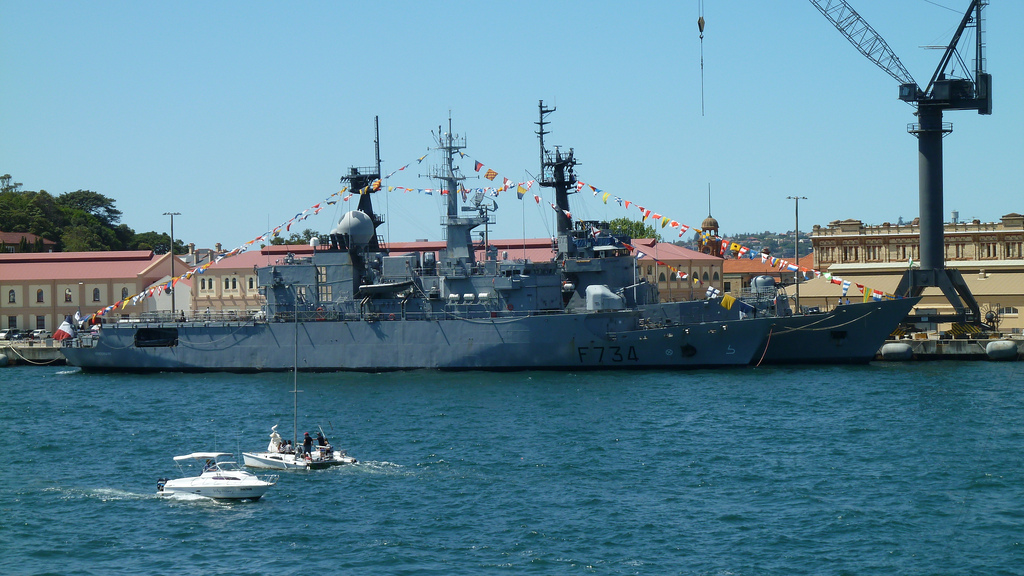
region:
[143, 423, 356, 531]
white boats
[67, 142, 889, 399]
large boat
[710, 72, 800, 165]
white clouds in blue sky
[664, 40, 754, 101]
white clouds in blue sky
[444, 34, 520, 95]
white clouds in blue sky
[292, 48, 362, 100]
white clouds in blue sky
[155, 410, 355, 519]
boats on the water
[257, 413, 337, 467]
people on the boat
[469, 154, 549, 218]
flags on the line above the boat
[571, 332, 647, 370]
F734 written on the side of the boat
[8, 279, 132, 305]
windows on the building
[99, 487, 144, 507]
white crashing waves on the water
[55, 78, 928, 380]
ship in the water in front of the houses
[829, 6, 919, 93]
crane in the air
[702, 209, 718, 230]
steeple on top of the building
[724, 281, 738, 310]
yellow flag on the boat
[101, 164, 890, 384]
large ship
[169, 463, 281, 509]
white boat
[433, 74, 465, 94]
white clouds in blue sky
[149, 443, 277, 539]
white boat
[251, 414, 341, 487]
boat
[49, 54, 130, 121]
white clouds in the blue sky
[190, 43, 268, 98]
white clouds in the blue sky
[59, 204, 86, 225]
green leaves on the tree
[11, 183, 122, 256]
green leaves on the tree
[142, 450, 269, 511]
small white boat in blue water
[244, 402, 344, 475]
small white boat in blue water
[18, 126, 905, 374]
large gray boat in blue water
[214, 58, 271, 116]
white clouds in blue sky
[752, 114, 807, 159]
white clouds in blue sky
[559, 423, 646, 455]
ripples in dark blue water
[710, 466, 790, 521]
ripples in dark blue water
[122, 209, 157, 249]
green leaves on the tree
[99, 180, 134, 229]
green leaves on the tree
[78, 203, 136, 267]
green leaves on the tree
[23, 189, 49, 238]
green leaves on the tree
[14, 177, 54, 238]
green leaves on the tree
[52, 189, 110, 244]
green leaves on the tree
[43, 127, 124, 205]
green leaves on the tree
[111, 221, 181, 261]
green leaves on the tree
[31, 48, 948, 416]
a pair of ships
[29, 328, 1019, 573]
a body of water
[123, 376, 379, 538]
two small boats in the water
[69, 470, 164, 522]
wave in the water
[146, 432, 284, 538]
the boat is white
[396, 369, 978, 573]
ripples in the water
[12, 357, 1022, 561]
the water is blue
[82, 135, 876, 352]
flags on the ship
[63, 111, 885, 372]
the ships are gray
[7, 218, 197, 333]
building in the background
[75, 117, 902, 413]
ship in the water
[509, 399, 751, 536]
ripples in the water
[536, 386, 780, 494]
blue water next to boat